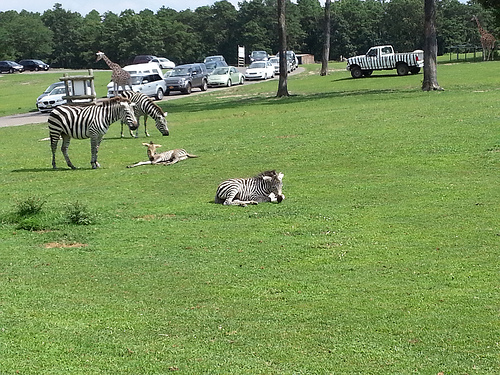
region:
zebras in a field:
[17, 43, 394, 328]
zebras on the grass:
[10, 34, 365, 301]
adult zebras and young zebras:
[37, 58, 384, 337]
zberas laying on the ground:
[136, 111, 361, 283]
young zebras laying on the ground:
[119, 119, 343, 264]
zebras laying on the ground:
[144, 100, 311, 242]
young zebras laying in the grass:
[128, 122, 351, 251]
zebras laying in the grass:
[118, 118, 354, 272]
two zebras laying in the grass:
[122, 123, 417, 298]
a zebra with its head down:
[97, 73, 215, 164]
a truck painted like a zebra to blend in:
[344, 42, 424, 78]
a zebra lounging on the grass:
[212, 168, 288, 205]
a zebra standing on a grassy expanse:
[45, 99, 140, 170]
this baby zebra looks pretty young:
[126, 138, 203, 168]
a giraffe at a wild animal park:
[93, 46, 138, 98]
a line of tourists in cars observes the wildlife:
[34, 48, 301, 114]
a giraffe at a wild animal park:
[468, 10, 498, 62]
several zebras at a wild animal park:
[46, 88, 286, 208]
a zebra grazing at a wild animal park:
[119, 88, 172, 139]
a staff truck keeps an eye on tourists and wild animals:
[343, 41, 429, 78]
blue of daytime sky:
[1, 0, 241, 15]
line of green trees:
[1, 0, 498, 68]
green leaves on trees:
[5, 11, 54, 58]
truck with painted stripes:
[346, 43, 422, 78]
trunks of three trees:
[277, 0, 439, 101]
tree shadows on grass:
[162, 87, 406, 117]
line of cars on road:
[42, 48, 300, 112]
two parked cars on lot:
[0, 56, 88, 74]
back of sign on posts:
[59, 68, 96, 103]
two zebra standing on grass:
[46, 90, 168, 170]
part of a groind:
[310, 68, 349, 126]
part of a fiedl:
[281, 276, 326, 338]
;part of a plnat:
[73, 200, 84, 219]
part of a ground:
[322, 282, 349, 342]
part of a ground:
[361, 249, 380, 286]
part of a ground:
[327, 298, 354, 353]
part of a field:
[320, 275, 371, 349]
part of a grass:
[342, 260, 374, 314]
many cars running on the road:
[63, 43, 270, 96]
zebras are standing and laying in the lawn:
[48, 88, 415, 265]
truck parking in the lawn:
[343, 41, 425, 68]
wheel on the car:
[155, 87, 168, 99]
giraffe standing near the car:
[94, 51, 144, 111]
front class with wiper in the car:
[166, 67, 193, 77]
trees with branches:
[260, 0, 292, 115]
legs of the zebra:
[86, 135, 106, 175]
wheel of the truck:
[393, 62, 411, 79]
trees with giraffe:
[470, 8, 495, 66]